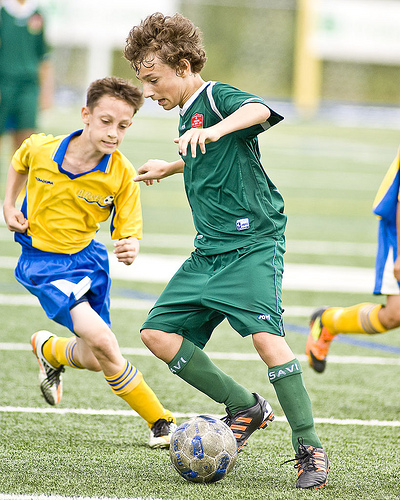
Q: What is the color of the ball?
A: White and blue.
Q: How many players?
A: 4.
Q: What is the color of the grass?
A: Green.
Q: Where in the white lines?
A: In the ground.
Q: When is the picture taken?
A: Daytime.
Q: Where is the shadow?
A: Ground.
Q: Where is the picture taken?
A: On a soccer field.